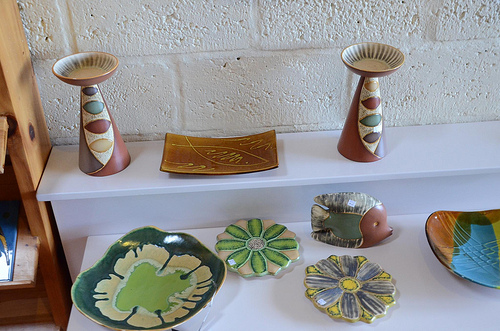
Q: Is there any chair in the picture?
A: No, there are no chairs.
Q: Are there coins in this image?
A: No, there are no coins.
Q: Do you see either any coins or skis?
A: No, there are no coins or skis.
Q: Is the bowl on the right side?
A: No, the bowl is on the left of the image.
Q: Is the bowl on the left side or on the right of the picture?
A: The bowl is on the left of the image.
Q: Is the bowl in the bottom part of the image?
A: Yes, the bowl is in the bottom of the image.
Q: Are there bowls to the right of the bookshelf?
A: Yes, there is a bowl to the right of the bookshelf.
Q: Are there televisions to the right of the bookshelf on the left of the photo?
A: No, there is a bowl to the right of the bookshelf.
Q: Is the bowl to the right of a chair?
A: No, the bowl is to the right of the bookshelf.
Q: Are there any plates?
A: Yes, there is a plate.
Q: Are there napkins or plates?
A: Yes, there is a plate.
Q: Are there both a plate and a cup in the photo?
A: No, there is a plate but no cups.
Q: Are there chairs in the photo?
A: No, there are no chairs.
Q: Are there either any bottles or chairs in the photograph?
A: No, there are no chairs or bottles.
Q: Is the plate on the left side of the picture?
A: No, the plate is on the right of the image.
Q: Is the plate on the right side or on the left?
A: The plate is on the right of the image.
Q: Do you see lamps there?
A: No, there are no lamps.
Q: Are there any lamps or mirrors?
A: No, there are no lamps or mirrors.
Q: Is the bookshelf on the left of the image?
A: Yes, the bookshelf is on the left of the image.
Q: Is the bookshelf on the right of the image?
A: No, the bookshelf is on the left of the image.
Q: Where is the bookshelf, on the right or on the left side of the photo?
A: The bookshelf is on the left of the image.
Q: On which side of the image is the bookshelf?
A: The bookshelf is on the left of the image.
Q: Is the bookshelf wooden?
A: Yes, the bookshelf is wooden.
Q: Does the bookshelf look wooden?
A: Yes, the bookshelf is wooden.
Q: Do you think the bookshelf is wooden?
A: Yes, the bookshelf is wooden.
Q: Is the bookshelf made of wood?
A: Yes, the bookshelf is made of wood.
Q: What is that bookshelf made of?
A: The bookshelf is made of wood.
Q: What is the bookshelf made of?
A: The bookshelf is made of wood.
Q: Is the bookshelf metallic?
A: No, the bookshelf is wooden.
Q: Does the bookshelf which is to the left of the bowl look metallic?
A: No, the bookshelf is wooden.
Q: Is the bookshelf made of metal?
A: No, the bookshelf is made of wood.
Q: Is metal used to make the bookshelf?
A: No, the bookshelf is made of wood.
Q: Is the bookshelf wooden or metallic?
A: The bookshelf is wooden.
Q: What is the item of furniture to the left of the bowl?
A: The piece of furniture is a bookshelf.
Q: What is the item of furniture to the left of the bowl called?
A: The piece of furniture is a bookshelf.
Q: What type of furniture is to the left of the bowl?
A: The piece of furniture is a bookshelf.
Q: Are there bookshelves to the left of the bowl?
A: Yes, there is a bookshelf to the left of the bowl.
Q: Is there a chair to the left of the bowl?
A: No, there is a bookshelf to the left of the bowl.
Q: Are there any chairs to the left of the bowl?
A: No, there is a bookshelf to the left of the bowl.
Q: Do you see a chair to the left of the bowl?
A: No, there is a bookshelf to the left of the bowl.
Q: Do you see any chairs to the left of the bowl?
A: No, there is a bookshelf to the left of the bowl.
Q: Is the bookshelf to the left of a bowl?
A: Yes, the bookshelf is to the left of a bowl.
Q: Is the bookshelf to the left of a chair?
A: No, the bookshelf is to the left of a bowl.